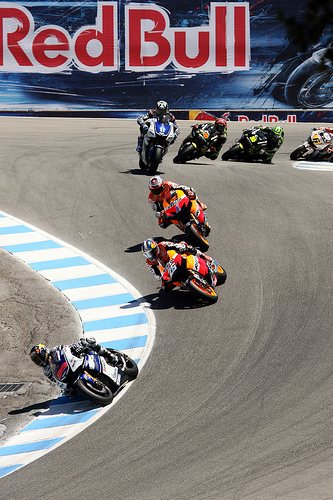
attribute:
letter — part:
[232, 1, 250, 72]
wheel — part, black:
[148, 139, 165, 173]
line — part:
[53, 252, 84, 273]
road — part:
[1, 114, 330, 499]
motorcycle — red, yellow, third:
[145, 176, 211, 253]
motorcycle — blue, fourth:
[137, 114, 178, 170]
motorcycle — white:
[290, 123, 331, 162]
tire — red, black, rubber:
[185, 224, 210, 253]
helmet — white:
[148, 171, 167, 197]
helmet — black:
[155, 98, 167, 112]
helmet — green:
[272, 123, 284, 139]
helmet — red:
[211, 113, 230, 134]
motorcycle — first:
[55, 339, 140, 407]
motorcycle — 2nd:
[141, 238, 226, 306]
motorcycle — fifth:
[174, 123, 221, 162]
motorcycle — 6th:
[221, 127, 271, 168]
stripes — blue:
[1, 209, 157, 479]